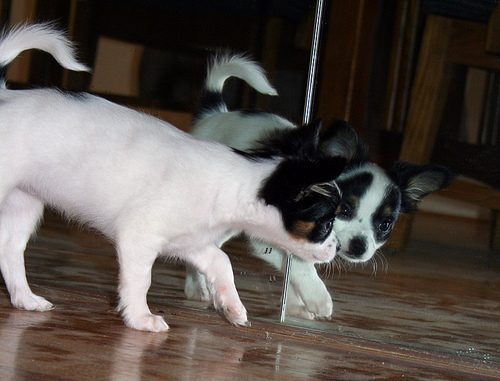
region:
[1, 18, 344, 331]
A black and white puppy.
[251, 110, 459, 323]
Reflection of a puppy.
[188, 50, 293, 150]
Hind end of a puppy.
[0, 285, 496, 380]
A shiny wood floor.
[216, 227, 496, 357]
Reflection of wood floor.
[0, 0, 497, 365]
A large room mirror.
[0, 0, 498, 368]
Reflection of a room in a mirror.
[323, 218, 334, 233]
A dark puppy eye.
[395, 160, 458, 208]
A black puppy ear.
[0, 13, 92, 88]
A white puppy tail.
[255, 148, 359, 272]
head of a dog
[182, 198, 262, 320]
leg of a dog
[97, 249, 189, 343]
leg of a dog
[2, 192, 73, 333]
leg of a dog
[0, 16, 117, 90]
tail of a dog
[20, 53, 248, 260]
body of a dog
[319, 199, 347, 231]
eye of a dog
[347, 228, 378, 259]
nose of a dog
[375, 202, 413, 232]
eye of a dog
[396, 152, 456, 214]
ear of a dog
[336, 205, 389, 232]
The eyes of the dog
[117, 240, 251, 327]
The front legs of the dog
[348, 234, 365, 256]
The nose of the dog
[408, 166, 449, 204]
The left ear of the dog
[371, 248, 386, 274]
the whiskers of the dog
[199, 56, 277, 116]
The tail of the dog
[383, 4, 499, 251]
A chair by the table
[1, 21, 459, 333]
Two dogs near a table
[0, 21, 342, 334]
A dog walking next to another dog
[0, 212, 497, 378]
The floor beneath the dogs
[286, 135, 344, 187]
ear of a dog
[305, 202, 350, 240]
eye of a dog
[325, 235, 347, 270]
nose of a dog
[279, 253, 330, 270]
mouth of a dog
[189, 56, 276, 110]
tail of a dog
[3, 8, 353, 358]
puppy looking in mirror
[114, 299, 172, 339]
puppy paw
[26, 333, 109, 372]
dust on hardwoood floor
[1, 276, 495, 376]
hardwood floors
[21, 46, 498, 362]
closet mirror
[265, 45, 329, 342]
line in middle of wall mirror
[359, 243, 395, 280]
white puppy whiskers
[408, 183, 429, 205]
white inside dog's ear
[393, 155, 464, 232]
black and white puppy ear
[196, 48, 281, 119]
puppy tail